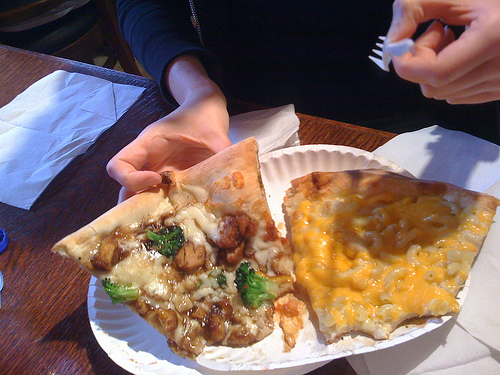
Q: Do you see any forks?
A: Yes, there is a fork.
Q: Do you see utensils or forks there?
A: Yes, there is a fork.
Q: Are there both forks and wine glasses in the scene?
A: No, there is a fork but no wine glasses.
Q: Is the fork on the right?
A: Yes, the fork is on the right of the image.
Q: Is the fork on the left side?
A: No, the fork is on the right of the image.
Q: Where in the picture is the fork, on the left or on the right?
A: The fork is on the right of the image.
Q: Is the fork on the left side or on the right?
A: The fork is on the right of the image.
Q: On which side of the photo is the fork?
A: The fork is on the right of the image.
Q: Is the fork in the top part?
A: Yes, the fork is in the top of the image.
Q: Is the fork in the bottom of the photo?
A: No, the fork is in the top of the image.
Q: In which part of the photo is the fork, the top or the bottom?
A: The fork is in the top of the image.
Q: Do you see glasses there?
A: No, there are no glasses.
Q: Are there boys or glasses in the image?
A: No, there are no glasses or boys.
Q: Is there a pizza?
A: Yes, there is a pizza.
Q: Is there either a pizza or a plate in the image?
A: Yes, there is a pizza.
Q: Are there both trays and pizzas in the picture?
A: No, there is a pizza but no trays.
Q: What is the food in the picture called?
A: The food is a pizza.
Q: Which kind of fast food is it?
A: The food is a pizza.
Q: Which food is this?
A: This is a pizza.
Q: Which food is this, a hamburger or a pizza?
A: This is a pizza.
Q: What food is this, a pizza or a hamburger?
A: This is a pizza.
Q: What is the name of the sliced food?
A: The food is a pizza.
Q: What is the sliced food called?
A: The food is a pizza.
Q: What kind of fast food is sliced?
A: The fast food is a pizza.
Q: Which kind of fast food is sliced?
A: The fast food is a pizza.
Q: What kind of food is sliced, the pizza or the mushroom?
A: The pizza is sliced.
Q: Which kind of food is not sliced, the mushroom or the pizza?
A: The mushroom is not sliced.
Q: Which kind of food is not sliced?
A: The food is a mushroom.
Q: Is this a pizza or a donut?
A: This is a pizza.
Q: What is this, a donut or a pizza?
A: This is a pizza.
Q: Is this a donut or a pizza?
A: This is a pizza.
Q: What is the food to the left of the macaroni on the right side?
A: The food is a pizza.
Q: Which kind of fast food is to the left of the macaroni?
A: The food is a pizza.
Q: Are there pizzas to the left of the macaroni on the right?
A: Yes, there is a pizza to the left of the macaroni.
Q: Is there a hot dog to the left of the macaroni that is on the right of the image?
A: No, there is a pizza to the left of the macaroni.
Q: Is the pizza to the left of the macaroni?
A: Yes, the pizza is to the left of the macaroni.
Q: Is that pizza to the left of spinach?
A: No, the pizza is to the left of the macaroni.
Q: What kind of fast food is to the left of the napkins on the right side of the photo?
A: The food is a pizza.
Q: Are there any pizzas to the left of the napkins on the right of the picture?
A: Yes, there is a pizza to the left of the napkins.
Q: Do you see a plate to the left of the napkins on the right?
A: No, there is a pizza to the left of the napkins.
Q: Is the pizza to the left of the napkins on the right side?
A: Yes, the pizza is to the left of the napkins.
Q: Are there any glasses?
A: No, there are no glasses.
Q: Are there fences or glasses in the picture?
A: No, there are no glasses or fences.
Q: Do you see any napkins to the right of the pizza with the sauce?
A: Yes, there are napkins to the right of the pizza.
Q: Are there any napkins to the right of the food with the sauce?
A: Yes, there are napkins to the right of the pizza.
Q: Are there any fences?
A: No, there are no fences.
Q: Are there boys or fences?
A: No, there are no fences or boys.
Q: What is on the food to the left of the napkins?
A: The sauce is on the pizza.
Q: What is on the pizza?
A: The sauce is on the pizza.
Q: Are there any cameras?
A: Yes, there is a camera.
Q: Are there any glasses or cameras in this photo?
A: Yes, there is a camera.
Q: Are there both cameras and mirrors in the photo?
A: No, there is a camera but no mirrors.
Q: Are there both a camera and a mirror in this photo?
A: No, there is a camera but no mirrors.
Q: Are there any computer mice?
A: No, there are no computer mice.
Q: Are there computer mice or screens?
A: No, there are no computer mice or screens.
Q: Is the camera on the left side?
A: Yes, the camera is on the left of the image.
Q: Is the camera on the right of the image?
A: No, the camera is on the left of the image.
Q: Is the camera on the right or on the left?
A: The camera is on the left of the image.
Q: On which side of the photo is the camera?
A: The camera is on the left of the image.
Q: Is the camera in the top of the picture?
A: Yes, the camera is in the top of the image.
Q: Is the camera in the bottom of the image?
A: No, the camera is in the top of the image.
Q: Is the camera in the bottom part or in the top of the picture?
A: The camera is in the top of the image.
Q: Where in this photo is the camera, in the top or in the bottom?
A: The camera is in the top of the image.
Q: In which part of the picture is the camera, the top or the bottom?
A: The camera is in the top of the image.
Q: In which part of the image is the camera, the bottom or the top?
A: The camera is in the top of the image.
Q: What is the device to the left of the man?
A: The device is a camera.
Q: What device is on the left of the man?
A: The device is a camera.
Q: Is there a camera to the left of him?
A: Yes, there is a camera to the left of the man.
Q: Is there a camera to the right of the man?
A: No, the camera is to the left of the man.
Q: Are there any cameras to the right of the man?
A: No, the camera is to the left of the man.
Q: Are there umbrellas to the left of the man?
A: No, there is a camera to the left of the man.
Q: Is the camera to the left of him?
A: Yes, the camera is to the left of a man.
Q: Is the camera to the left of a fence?
A: No, the camera is to the left of a man.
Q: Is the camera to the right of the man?
A: No, the camera is to the left of the man.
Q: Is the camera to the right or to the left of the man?
A: The camera is to the left of the man.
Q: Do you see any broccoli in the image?
A: Yes, there is broccoli.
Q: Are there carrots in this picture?
A: No, there are no carrots.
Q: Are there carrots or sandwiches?
A: No, there are no carrots or sandwiches.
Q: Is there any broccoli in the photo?
A: Yes, there is broccoli.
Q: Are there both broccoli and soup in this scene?
A: No, there is broccoli but no soup.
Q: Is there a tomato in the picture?
A: No, there are no tomatoes.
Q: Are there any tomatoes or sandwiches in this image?
A: No, there are no tomatoes or sandwiches.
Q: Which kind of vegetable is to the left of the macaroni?
A: The vegetable is broccoli.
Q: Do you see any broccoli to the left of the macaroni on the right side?
A: Yes, there is broccoli to the left of the macaroni.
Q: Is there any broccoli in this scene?
A: Yes, there is broccoli.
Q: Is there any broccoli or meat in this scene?
A: Yes, there is broccoli.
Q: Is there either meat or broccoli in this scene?
A: Yes, there is broccoli.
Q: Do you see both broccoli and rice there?
A: No, there is broccoli but no rice.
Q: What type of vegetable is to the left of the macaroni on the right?
A: The vegetable is broccoli.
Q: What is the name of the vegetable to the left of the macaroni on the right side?
A: The vegetable is broccoli.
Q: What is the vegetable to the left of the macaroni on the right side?
A: The vegetable is broccoli.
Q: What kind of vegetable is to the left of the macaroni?
A: The vegetable is broccoli.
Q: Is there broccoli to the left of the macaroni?
A: Yes, there is broccoli to the left of the macaroni.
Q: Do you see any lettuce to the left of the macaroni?
A: No, there is broccoli to the left of the macaroni.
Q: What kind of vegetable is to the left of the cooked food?
A: The vegetable is broccoli.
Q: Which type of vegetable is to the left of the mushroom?
A: The vegetable is broccoli.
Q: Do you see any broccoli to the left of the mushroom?
A: Yes, there is broccoli to the left of the mushroom.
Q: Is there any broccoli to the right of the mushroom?
A: No, the broccoli is to the left of the mushroom.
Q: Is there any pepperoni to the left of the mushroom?
A: No, there is broccoli to the left of the mushroom.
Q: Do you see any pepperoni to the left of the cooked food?
A: No, there is broccoli to the left of the mushroom.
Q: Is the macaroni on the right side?
A: Yes, the macaroni is on the right of the image.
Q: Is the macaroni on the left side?
A: No, the macaroni is on the right of the image.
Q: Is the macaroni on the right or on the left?
A: The macaroni is on the right of the image.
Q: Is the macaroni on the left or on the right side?
A: The macaroni is on the right of the image.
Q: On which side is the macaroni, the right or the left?
A: The macaroni is on the right of the image.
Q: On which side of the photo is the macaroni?
A: The macaroni is on the right of the image.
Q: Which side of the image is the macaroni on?
A: The macaroni is on the right of the image.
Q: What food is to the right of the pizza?
A: The food is macaroni.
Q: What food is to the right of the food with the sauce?
A: The food is macaroni.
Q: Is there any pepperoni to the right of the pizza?
A: No, there is macaroni to the right of the pizza.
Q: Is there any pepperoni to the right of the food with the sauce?
A: No, there is macaroni to the right of the pizza.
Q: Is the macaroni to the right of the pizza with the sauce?
A: Yes, the macaroni is to the right of the pizza.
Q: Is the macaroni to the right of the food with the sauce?
A: Yes, the macaroni is to the right of the pizza.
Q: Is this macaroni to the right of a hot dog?
A: No, the macaroni is to the right of the pizza.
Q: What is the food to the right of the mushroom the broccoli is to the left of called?
A: The food is macaroni.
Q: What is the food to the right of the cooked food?
A: The food is macaroni.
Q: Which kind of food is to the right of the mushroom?
A: The food is macaroni.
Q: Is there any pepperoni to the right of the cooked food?
A: No, there is macaroni to the right of the mushroom.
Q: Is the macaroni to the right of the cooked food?
A: Yes, the macaroni is to the right of the mushroom.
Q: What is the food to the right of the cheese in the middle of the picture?
A: The food is macaroni.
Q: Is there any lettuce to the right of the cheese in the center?
A: No, there is macaroni to the right of the cheese.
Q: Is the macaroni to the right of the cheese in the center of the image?
A: Yes, the macaroni is to the right of the cheese.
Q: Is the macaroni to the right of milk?
A: No, the macaroni is to the right of the cheese.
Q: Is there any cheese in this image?
A: Yes, there is cheese.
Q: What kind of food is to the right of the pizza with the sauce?
A: The food is cheese.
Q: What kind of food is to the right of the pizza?
A: The food is cheese.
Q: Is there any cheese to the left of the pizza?
A: No, the cheese is to the right of the pizza.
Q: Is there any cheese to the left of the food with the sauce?
A: No, the cheese is to the right of the pizza.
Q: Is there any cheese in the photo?
A: Yes, there is cheese.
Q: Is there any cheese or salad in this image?
A: Yes, there is cheese.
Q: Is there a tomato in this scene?
A: No, there are no tomatoes.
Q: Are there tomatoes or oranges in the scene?
A: No, there are no tomatoes or oranges.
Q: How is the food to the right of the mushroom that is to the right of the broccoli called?
A: The food is cheese.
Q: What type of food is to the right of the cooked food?
A: The food is cheese.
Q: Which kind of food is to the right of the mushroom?
A: The food is cheese.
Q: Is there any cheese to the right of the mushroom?
A: Yes, there is cheese to the right of the mushroom.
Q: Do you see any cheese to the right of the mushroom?
A: Yes, there is cheese to the right of the mushroom.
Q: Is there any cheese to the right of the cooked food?
A: Yes, there is cheese to the right of the mushroom.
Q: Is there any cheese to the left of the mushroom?
A: No, the cheese is to the right of the mushroom.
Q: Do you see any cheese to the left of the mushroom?
A: No, the cheese is to the right of the mushroom.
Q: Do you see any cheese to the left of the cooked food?
A: No, the cheese is to the right of the mushroom.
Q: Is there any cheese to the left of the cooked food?
A: No, the cheese is to the right of the mushroom.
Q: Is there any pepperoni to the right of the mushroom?
A: No, there is cheese to the right of the mushroom.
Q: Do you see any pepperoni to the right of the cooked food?
A: No, there is cheese to the right of the mushroom.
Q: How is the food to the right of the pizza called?
A: The food is cheese.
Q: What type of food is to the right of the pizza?
A: The food is cheese.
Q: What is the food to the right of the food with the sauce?
A: The food is cheese.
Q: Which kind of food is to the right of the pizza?
A: The food is cheese.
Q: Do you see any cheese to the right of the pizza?
A: Yes, there is cheese to the right of the pizza.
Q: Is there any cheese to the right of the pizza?
A: Yes, there is cheese to the right of the pizza.